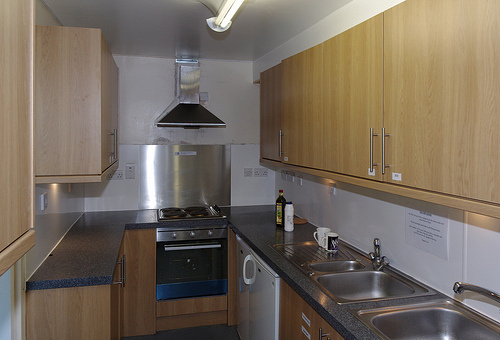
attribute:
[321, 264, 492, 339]
sink — close, silver, gray, grey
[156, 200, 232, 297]
stove — combination, silver, kitchen, black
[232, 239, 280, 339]
dishwasher — coffee, white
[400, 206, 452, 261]
paper — peice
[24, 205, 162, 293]
counter — kitchen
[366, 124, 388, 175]
handle — metal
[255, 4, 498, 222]
cabinets — brown, counter, kitchen, close, big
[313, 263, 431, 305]
sink — kitchen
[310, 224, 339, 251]
cups — empty, coffee